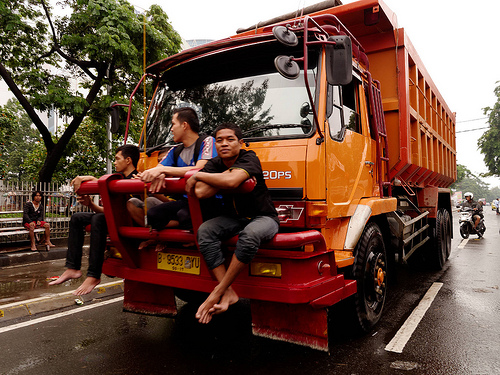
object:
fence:
[0, 181, 99, 244]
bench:
[0, 226, 53, 252]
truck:
[72, 0, 457, 353]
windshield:
[137, 38, 325, 152]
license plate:
[156, 252, 201, 276]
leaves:
[110, 39, 122, 49]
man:
[141, 106, 217, 232]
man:
[45, 143, 147, 295]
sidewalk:
[0, 237, 126, 326]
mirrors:
[273, 55, 301, 82]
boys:
[186, 124, 280, 326]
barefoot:
[72, 273, 103, 298]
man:
[458, 190, 484, 230]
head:
[463, 191, 474, 201]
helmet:
[463, 192, 473, 201]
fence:
[2, 170, 92, 240]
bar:
[0, 228, 50, 252]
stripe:
[383, 282, 446, 354]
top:
[215, 125, 236, 132]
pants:
[63, 212, 107, 277]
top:
[168, 106, 198, 115]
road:
[0, 204, 500, 375]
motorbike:
[456, 204, 486, 239]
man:
[22, 189, 57, 251]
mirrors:
[272, 24, 299, 48]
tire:
[336, 223, 389, 334]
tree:
[0, 0, 182, 210]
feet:
[208, 288, 239, 317]